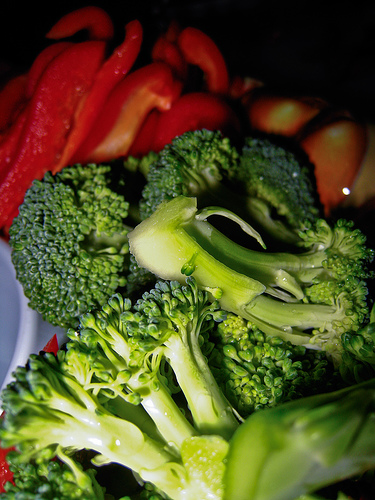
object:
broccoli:
[127, 193, 373, 377]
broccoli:
[139, 127, 310, 253]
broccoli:
[228, 137, 320, 244]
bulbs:
[21, 227, 84, 285]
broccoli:
[9, 174, 372, 469]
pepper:
[0, 6, 240, 243]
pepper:
[6, 48, 97, 236]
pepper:
[79, 25, 136, 166]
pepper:
[103, 64, 163, 169]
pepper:
[174, 23, 235, 104]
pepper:
[148, 32, 183, 98]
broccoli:
[9, 140, 352, 488]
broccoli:
[117, 188, 374, 370]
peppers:
[1, 3, 230, 240]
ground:
[313, 87, 332, 109]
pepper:
[1, 40, 106, 242]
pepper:
[52, 18, 141, 173]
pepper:
[0, 101, 28, 183]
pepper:
[24, 40, 77, 103]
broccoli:
[11, 168, 366, 499]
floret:
[219, 341, 261, 384]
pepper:
[7, 6, 197, 165]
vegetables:
[7, 40, 374, 475]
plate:
[0, 236, 72, 390]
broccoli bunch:
[23, 235, 289, 498]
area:
[166, 433, 241, 498]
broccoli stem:
[191, 354, 373, 497]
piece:
[11, 158, 158, 332]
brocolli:
[6, 162, 142, 313]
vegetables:
[49, 34, 316, 464]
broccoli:
[0, 127, 372, 494]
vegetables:
[34, 129, 359, 471]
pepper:
[0, 42, 106, 230]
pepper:
[67, 62, 182, 164]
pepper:
[151, 91, 229, 153]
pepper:
[178, 27, 227, 93]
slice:
[122, 68, 198, 122]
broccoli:
[0, 157, 138, 346]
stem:
[171, 349, 223, 401]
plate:
[0, 232, 72, 421]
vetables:
[6, 130, 372, 495]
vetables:
[0, 6, 249, 248]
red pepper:
[41, 333, 62, 358]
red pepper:
[5, 0, 367, 244]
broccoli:
[292, 204, 355, 270]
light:
[39, 329, 219, 500]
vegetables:
[2, 4, 375, 496]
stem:
[161, 331, 241, 446]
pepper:
[3, 7, 374, 242]